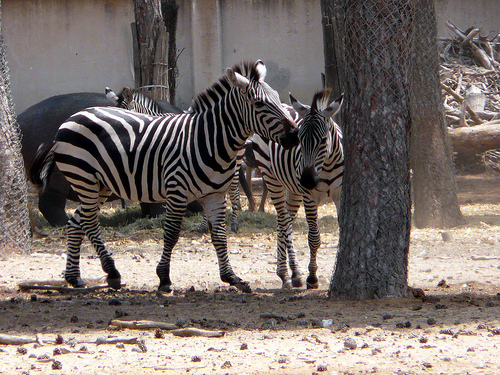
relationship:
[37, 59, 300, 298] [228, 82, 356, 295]
zebra next to zebra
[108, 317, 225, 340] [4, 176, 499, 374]
sticks on ground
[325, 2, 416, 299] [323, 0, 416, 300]
tree has pattern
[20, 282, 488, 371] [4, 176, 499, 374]
rocks on ground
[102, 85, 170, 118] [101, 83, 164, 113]
zebra has head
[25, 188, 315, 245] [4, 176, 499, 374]
grass on ground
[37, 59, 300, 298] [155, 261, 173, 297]
zebra has hoof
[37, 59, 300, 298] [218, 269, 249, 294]
zebra has hoof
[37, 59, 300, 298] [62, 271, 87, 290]
zebra has hoof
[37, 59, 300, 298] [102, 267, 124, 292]
zebra has hoof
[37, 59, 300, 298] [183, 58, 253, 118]
zebra has mane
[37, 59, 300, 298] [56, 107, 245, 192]
zebra has stripes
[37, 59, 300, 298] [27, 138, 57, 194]
zebra has tail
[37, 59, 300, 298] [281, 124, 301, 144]
zebra has nose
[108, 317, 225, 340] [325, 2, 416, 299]
branches are from tree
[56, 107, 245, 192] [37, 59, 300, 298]
stripes on zebra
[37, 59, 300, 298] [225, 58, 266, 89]
zebra has ears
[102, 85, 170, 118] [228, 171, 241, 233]
zebra has leg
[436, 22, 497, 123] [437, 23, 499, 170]
wood in pile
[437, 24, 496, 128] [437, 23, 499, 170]
sticks in pile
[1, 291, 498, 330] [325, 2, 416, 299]
shadow under tree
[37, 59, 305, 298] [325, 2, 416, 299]
zebra near tree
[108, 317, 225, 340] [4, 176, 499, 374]
sticks in dirt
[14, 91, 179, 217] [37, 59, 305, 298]
animal behind zebra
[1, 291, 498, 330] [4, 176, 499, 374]
shadow on ground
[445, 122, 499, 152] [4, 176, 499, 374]
log on ground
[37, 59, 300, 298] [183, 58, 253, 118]
zebra has hair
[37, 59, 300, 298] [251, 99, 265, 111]
zebra has eye